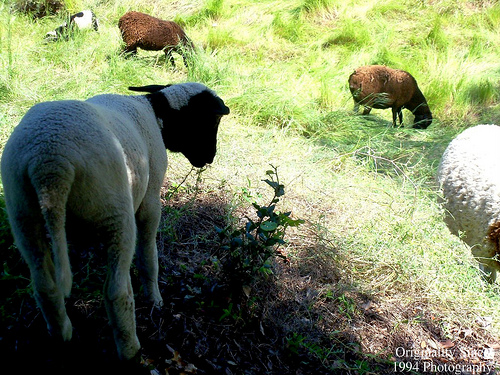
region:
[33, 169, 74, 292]
The tail of the sheep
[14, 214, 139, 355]
The back legs of the sheep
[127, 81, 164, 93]
The left ear of the sheep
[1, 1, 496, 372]
Grass beneath the sheep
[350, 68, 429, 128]
The sheep is eating the grass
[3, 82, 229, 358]
The sheep is standing in the grass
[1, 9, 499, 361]
The sheep are in a grassy area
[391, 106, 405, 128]
The front legs of the sheep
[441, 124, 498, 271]
The sheep has white fur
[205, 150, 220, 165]
The nose of the sheep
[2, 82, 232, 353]
a sheep standing around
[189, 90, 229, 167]
the face is dark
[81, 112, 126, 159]
the wool is white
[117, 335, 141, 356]
hoof of a sheep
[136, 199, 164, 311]
leg of a sheep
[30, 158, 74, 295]
sheep's tail hanging down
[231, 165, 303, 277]
a large green weed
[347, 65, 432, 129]
the sheep is brown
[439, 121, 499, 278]
part of a white sheep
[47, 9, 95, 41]
the sheep is lying down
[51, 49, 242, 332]
white sheep on hill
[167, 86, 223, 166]
sheep has black face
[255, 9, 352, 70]
green and thick grass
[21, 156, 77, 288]
sheep has white tail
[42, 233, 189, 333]
sheep has white legs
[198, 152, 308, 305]
green plant on hill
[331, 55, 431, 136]
sheep has brown wool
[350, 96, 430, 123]
sheep has brown legs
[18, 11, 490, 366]
sheep are in the pasture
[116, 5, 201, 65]
the sheep is brown in color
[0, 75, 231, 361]
the sheep is white with a partial black head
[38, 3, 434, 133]
the sheep are grazing in the pasture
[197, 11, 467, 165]
the grass is long in the pasture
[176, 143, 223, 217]
the sheep eats these leaves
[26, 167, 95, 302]
the sheep has a long tail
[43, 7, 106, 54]
the sheep has black and white wool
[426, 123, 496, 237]
the sheep has white wool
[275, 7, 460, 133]
the grass is green and yellow in color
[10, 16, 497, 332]
animal in the background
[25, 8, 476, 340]
wild life in the background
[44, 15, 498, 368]
sheep in the background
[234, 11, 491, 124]
grass on the ground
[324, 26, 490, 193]
sheep eating grass on the ground